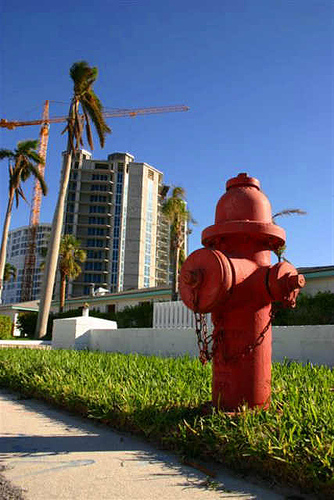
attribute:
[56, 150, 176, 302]
white building — blue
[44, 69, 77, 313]
trees — several, tall, palm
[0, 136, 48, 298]
tree — tall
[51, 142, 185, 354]
building — tall, white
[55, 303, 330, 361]
wall — white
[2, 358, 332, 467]
grass — green, lush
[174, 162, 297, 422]
hydrant — fire hydrant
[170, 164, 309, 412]
fire hydrant — red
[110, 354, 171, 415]
grass — green, tall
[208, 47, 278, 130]
sky — blue, bright, without clouds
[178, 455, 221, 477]
bolt — rusty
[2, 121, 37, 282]
tree — palm tree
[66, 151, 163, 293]
building — tall, huge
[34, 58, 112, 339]
tree — tall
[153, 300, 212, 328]
fence — white, wooden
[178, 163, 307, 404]
firehydrant — fire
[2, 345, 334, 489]
grass — green, bright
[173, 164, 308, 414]
hydrant — red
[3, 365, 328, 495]
sidewalk — light, brown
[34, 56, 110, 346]
palm tree — long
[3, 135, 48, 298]
palm tree — long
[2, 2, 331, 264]
sky — light blue, cloudless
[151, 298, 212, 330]
fence — white, picket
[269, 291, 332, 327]
shrubbery — dark, green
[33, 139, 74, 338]
trunk — long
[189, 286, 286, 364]
chains — red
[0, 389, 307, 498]
footpath — Concrete